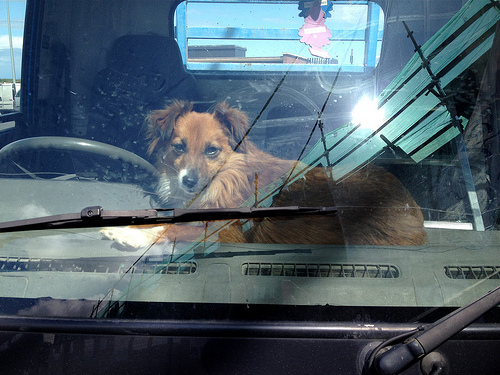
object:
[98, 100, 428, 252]
dog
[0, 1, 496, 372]
car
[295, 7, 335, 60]
air freshener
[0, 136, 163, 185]
steering wheel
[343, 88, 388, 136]
sun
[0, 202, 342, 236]
whipper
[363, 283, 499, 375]
whipper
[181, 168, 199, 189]
nose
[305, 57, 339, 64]
fence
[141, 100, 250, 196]
head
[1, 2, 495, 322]
windscreen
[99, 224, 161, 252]
paw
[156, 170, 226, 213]
chest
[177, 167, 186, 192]
white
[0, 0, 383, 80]
sky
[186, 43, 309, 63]
object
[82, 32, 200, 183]
seat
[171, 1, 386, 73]
rear glass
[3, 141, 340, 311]
right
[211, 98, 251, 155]
ear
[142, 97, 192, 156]
ear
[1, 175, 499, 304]
dashboard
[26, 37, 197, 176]
diver side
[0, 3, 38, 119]
window